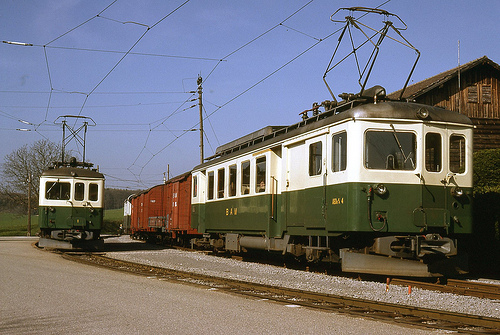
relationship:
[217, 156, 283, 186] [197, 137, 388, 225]
windows on cars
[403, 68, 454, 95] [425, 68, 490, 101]
roof of building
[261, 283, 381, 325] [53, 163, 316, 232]
tracks on train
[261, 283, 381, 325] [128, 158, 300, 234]
tracks for trolleys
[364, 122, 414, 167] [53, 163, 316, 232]
windshield on train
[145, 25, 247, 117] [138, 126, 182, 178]
sky has clouds